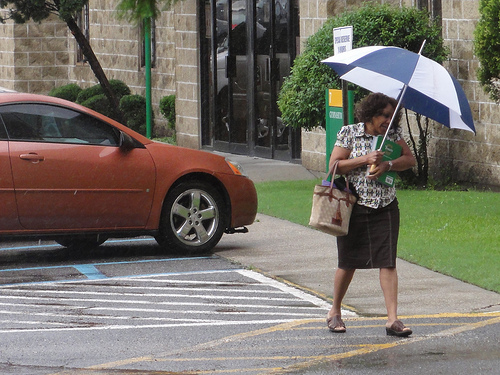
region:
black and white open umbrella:
[325, 38, 487, 115]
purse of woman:
[311, 188, 355, 243]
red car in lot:
[1, 76, 259, 236]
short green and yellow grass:
[462, 246, 484, 270]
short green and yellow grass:
[430, 202, 474, 237]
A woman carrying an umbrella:
[275, 31, 466, 349]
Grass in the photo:
[420, 187, 478, 262]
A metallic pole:
[135, 34, 165, 143]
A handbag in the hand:
[305, 149, 360, 241]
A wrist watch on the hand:
[384, 154, 394, 179]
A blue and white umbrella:
[335, 31, 474, 114]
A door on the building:
[217, 22, 276, 128]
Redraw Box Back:
[288, 338, 303, 360]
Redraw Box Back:
[296, 336, 317, 373]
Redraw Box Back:
[302, 334, 332, 358]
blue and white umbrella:
[360, 40, 465, 112]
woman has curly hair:
[357, 92, 406, 128]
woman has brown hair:
[339, 87, 402, 112]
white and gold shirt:
[344, 90, 422, 209]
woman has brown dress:
[350, 204, 413, 278]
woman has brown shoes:
[368, 317, 421, 342]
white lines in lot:
[104, 230, 334, 344]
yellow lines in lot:
[174, 285, 381, 370]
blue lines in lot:
[2, 240, 225, 285]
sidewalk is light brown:
[226, 208, 306, 267]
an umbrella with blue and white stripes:
[318, 36, 479, 180]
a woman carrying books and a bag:
[303, 92, 414, 339]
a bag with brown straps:
[307, 158, 359, 239]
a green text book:
[363, 135, 403, 191]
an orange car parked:
[0, 90, 260, 260]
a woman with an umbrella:
[305, 36, 477, 336]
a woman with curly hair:
[324, 91, 412, 338]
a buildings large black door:
[190, 1, 307, 168]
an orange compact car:
[1, 88, 258, 256]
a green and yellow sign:
[320, 86, 355, 173]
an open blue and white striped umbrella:
[317, 37, 477, 132]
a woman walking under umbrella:
[308, 38, 478, 338]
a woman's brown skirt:
[334, 199, 401, 269]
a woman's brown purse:
[311, 159, 358, 235]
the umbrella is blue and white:
[322, 35, 475, 175]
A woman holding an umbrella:
[305, 30, 485, 343]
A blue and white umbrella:
[310, 31, 480, 141]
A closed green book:
[367, 132, 404, 189]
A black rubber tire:
[147, 170, 229, 256]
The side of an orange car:
[0, 82, 261, 254]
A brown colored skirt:
[330, 192, 405, 272]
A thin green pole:
[135, 11, 155, 142]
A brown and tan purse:
[301, 156, 362, 241]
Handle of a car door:
[13, 146, 46, 166]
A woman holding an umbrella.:
[315, 35, 475, 343]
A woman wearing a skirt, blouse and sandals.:
[310, 90, 420, 340]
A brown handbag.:
[307, 161, 359, 239]